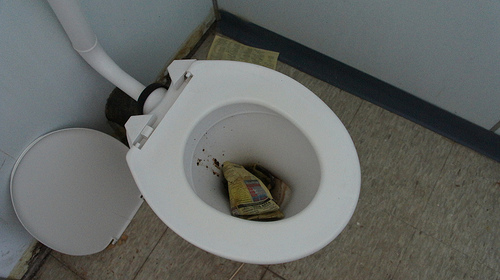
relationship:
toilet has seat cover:
[123, 57, 365, 268] [7, 125, 146, 257]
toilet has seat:
[123, 57, 365, 268] [127, 63, 362, 266]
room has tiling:
[1, 1, 500, 279] [30, 33, 499, 278]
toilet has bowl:
[123, 57, 365, 268] [183, 101, 323, 223]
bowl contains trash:
[183, 101, 323, 223] [221, 159, 294, 223]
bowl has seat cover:
[183, 101, 323, 223] [7, 125, 146, 257]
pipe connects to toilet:
[47, 0, 146, 100] [123, 57, 365, 268]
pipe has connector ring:
[47, 0, 146, 100] [137, 82, 169, 114]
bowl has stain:
[183, 101, 323, 223] [195, 156, 201, 167]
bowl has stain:
[183, 101, 323, 223] [212, 156, 220, 169]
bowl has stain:
[183, 101, 323, 223] [211, 169, 220, 178]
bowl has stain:
[183, 101, 323, 223] [202, 147, 212, 158]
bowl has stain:
[183, 101, 323, 223] [204, 165, 210, 169]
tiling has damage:
[30, 33, 499, 278] [9, 242, 88, 280]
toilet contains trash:
[123, 57, 365, 268] [221, 159, 294, 223]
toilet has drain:
[123, 57, 365, 268] [223, 165, 271, 200]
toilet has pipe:
[123, 57, 365, 268] [47, 0, 146, 100]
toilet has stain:
[123, 57, 365, 268] [212, 156, 220, 169]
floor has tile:
[30, 33, 499, 278] [387, 228, 499, 279]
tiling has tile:
[30, 33, 499, 278] [416, 143, 499, 272]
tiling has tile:
[30, 33, 499, 278] [346, 99, 456, 229]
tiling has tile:
[30, 33, 499, 278] [387, 228, 499, 279]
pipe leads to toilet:
[47, 0, 146, 100] [123, 57, 365, 268]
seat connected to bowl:
[127, 63, 362, 266] [183, 101, 323, 223]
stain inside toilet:
[195, 156, 201, 167] [123, 57, 365, 268]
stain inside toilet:
[204, 165, 210, 169] [123, 57, 365, 268]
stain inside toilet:
[211, 169, 220, 178] [123, 57, 365, 268]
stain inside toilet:
[202, 147, 212, 158] [123, 57, 365, 268]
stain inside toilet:
[212, 156, 220, 169] [123, 57, 365, 268]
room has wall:
[1, 1, 500, 279] [1, 0, 220, 279]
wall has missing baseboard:
[1, 0, 220, 279] [10, 7, 219, 279]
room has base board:
[1, 1, 500, 279] [213, 8, 499, 162]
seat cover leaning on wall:
[7, 125, 146, 257] [1, 0, 220, 279]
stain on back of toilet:
[195, 156, 201, 167] [123, 57, 365, 268]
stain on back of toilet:
[204, 165, 210, 169] [123, 57, 365, 268]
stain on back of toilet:
[211, 169, 220, 178] [123, 57, 365, 268]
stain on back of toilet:
[202, 147, 212, 158] [123, 57, 365, 268]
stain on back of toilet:
[212, 156, 220, 169] [123, 57, 365, 268]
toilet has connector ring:
[123, 57, 365, 268] [137, 82, 169, 114]